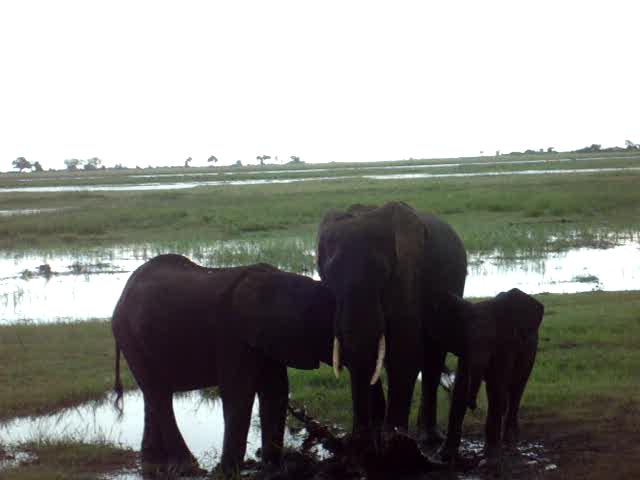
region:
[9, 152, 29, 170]
tree off in the distance behind the elephant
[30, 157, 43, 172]
tree off in the distance behind the elephant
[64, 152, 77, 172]
tree off in the distance behind the elephant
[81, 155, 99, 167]
tree off in the distance behind the elephant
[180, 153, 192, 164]
tree off in the distance behind the elephant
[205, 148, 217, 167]
tree off in the distance behind the elephant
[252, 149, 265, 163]
tree off in the distance behind the elephant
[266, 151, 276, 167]
tree off in the distance behind the elephant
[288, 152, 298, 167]
tree off in the distance behind the elephant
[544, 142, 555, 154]
tree off in the distance behind the elephant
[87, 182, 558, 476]
three elephants in a field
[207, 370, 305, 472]
front legs of elephant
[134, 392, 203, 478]
back legs of elephant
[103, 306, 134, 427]
long tail of elephant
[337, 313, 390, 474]
the trunk of elephant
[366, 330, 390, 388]
tusk of elephant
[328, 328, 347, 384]
tusk of elephant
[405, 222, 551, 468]
a baby elephant next to his mother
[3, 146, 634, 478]
the field is covered with water and grass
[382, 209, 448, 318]
the ear of an elephant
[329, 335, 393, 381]
Tusks on an elephant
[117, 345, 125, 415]
A tail on an elephant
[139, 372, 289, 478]
Legs on an elephant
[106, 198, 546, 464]
Three elephants in a wet field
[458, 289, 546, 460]
A baby gray elephant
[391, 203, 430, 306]
An ear on an elephant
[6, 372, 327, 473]
A puddle of water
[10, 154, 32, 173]
A tree in a field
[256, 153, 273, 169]
A tree in a field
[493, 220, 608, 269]
Grass in a patch of water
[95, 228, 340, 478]
gray elephant standing in water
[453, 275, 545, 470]
gray elephant standing in water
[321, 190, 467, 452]
gray elephant standing in water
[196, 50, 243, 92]
white clouds in blue sky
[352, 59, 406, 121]
white clouds in blue sky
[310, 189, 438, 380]
gray elephant standing in water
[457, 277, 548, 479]
gray elephant standing in water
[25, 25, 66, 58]
white clouds in blue sky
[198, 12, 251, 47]
white clouds in blue sky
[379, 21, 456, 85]
white clouds in blue sky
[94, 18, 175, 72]
white clouds in blue sky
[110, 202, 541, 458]
elephants standing in a marshy place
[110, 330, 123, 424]
the tail has long hair at the end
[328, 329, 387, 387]
the tusks are white and made of ivory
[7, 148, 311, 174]
trees in the distance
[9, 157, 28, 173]
the tree has leaves on it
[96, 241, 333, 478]
the elephant is standing in the water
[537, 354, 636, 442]
the dirt is next to the grass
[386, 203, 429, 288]
the ear is large and gray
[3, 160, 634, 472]
grass growing in a marshy area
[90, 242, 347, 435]
An animal in a field.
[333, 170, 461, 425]
An animal in a field.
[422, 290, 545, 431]
An animal in a field.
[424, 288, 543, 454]
A large grey elephant.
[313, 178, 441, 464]
A large grey elephant.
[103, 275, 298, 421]
A large grey elephant.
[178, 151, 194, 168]
A tree in a field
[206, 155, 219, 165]
A tree in a field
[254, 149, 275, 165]
A tree in a field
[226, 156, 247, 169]
A tree in a field